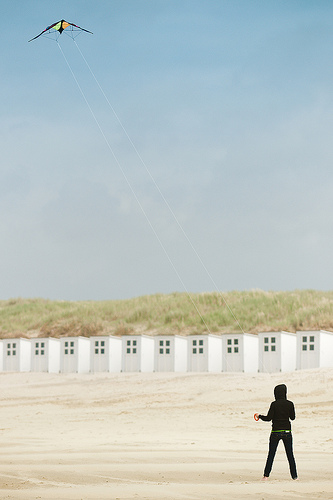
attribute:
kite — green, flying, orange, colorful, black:
[28, 18, 95, 43]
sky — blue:
[1, 0, 331, 300]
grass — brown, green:
[1, 290, 332, 338]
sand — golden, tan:
[0, 368, 332, 500]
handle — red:
[253, 412, 260, 422]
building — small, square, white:
[295, 328, 332, 371]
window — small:
[226, 338, 240, 354]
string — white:
[56, 40, 261, 417]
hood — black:
[273, 384, 287, 401]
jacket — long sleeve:
[258, 384, 296, 430]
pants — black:
[263, 430, 298, 480]